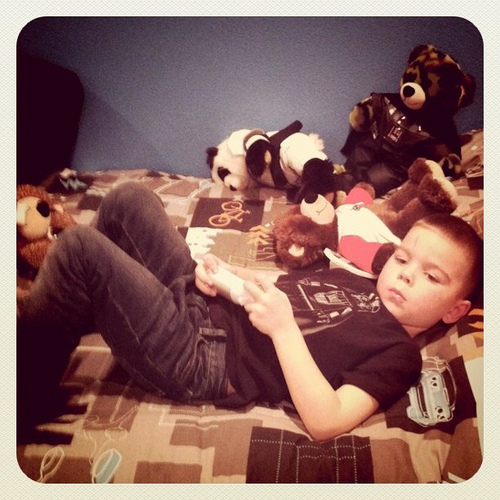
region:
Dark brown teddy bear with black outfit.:
[345, 42, 473, 187]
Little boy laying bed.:
[23, 179, 478, 444]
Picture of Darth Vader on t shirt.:
[290, 273, 380, 333]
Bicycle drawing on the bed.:
[189, 195, 262, 231]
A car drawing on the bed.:
[403, 367, 453, 426]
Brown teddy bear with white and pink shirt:
[272, 159, 455, 270]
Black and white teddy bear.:
[203, 121, 341, 192]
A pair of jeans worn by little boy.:
[28, 175, 225, 405]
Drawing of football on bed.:
[44, 167, 100, 199]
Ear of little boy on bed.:
[435, 296, 473, 333]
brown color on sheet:
[224, 431, 303, 463]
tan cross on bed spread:
[52, 397, 223, 474]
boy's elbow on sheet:
[291, 417, 340, 439]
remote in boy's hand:
[185, 252, 256, 309]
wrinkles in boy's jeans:
[125, 304, 199, 359]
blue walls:
[171, 77, 266, 98]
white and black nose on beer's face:
[369, 75, 434, 115]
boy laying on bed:
[100, 179, 442, 399]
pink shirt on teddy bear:
[322, 186, 384, 266]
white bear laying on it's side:
[191, 117, 346, 197]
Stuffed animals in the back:
[101, 78, 476, 314]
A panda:
[158, 86, 364, 233]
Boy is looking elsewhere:
[348, 182, 478, 344]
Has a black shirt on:
[199, 227, 419, 439]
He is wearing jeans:
[41, 166, 266, 447]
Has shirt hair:
[388, 175, 485, 344]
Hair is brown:
[393, 205, 482, 311]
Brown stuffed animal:
[249, 174, 465, 301]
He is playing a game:
[186, 229, 383, 444]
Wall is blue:
[94, 34, 199, 152]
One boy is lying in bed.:
[48, 206, 467, 421]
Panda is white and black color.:
[194, 131, 329, 198]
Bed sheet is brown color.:
[184, 403, 351, 487]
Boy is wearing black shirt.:
[272, 197, 462, 259]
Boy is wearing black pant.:
[52, 211, 201, 370]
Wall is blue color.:
[95, 38, 240, 121]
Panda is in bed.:
[213, 111, 347, 202]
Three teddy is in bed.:
[24, 80, 439, 280]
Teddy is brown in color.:
[348, 48, 456, 180]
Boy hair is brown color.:
[436, 213, 498, 254]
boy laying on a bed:
[36, 192, 457, 429]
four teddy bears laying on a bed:
[16, 32, 472, 269]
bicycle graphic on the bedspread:
[208, 197, 250, 224]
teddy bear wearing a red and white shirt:
[275, 180, 455, 265]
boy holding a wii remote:
[196, 209, 478, 326]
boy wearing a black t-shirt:
[268, 215, 482, 430]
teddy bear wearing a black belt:
[261, 120, 303, 198]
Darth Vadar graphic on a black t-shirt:
[280, 275, 382, 335]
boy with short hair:
[379, 212, 474, 326]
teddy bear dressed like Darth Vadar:
[331, 44, 468, 194]